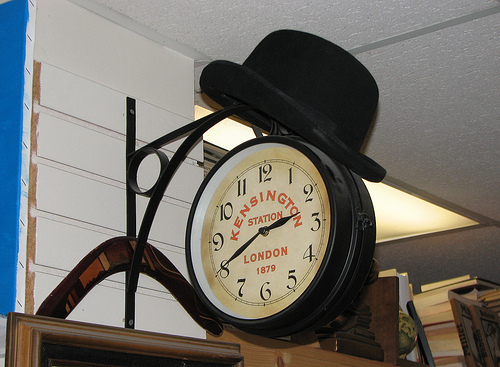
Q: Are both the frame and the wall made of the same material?
A: Yes, both the frame and the wall are made of wood.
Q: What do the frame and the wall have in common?
A: The material, both the frame and the wall are wooden.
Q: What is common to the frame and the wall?
A: The material, both the frame and the wall are wooden.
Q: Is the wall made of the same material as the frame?
A: Yes, both the wall and the frame are made of wood.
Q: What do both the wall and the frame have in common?
A: The material, both the wall and the frame are wooden.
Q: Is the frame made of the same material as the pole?
A: No, the frame is made of wood and the pole is made of metal.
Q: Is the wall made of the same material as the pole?
A: No, the wall is made of wood and the pole is made of metal.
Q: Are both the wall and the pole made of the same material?
A: No, the wall is made of wood and the pole is made of metal.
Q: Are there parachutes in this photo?
A: No, there are no parachutes.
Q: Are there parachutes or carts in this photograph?
A: No, there are no parachutes or carts.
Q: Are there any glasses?
A: No, there are no glasses.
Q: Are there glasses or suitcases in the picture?
A: No, there are no glasses or suitcases.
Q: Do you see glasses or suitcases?
A: No, there are no glasses or suitcases.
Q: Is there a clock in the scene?
A: Yes, there is a clock.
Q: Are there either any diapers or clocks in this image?
A: Yes, there is a clock.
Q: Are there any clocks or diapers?
A: Yes, there is a clock.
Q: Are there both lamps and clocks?
A: No, there is a clock but no lamps.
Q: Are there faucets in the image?
A: No, there are no faucets.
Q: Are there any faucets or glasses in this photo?
A: No, there are no faucets or glasses.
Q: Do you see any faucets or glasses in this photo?
A: No, there are no faucets or glasses.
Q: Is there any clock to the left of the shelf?
A: Yes, there is a clock to the left of the shelf.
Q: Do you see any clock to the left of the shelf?
A: Yes, there is a clock to the left of the shelf.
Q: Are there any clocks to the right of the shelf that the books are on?
A: No, the clock is to the left of the shelf.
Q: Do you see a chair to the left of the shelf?
A: No, there is a clock to the left of the shelf.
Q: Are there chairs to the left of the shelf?
A: No, there is a clock to the left of the shelf.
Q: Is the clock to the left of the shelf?
A: Yes, the clock is to the left of the shelf.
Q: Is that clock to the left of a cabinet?
A: No, the clock is to the left of the shelf.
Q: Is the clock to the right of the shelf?
A: No, the clock is to the left of the shelf.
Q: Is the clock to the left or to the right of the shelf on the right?
A: The clock is to the left of the shelf.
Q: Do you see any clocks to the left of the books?
A: Yes, there is a clock to the left of the books.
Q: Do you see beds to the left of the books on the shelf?
A: No, there is a clock to the left of the books.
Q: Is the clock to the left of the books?
A: Yes, the clock is to the left of the books.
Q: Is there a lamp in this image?
A: No, there are no lamps.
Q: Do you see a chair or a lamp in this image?
A: No, there are no lamps or chairs.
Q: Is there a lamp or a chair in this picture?
A: No, there are no lamps or chairs.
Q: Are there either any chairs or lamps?
A: No, there are no lamps or chairs.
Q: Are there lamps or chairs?
A: No, there are no lamps or chairs.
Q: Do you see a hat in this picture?
A: Yes, there is a hat.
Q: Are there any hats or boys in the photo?
A: Yes, there is a hat.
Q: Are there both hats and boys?
A: No, there is a hat but no boys.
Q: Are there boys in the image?
A: No, there are no boys.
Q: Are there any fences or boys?
A: No, there are no boys or fences.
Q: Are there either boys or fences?
A: No, there are no boys or fences.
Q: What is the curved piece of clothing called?
A: The clothing item is a hat.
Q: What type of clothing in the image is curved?
A: The clothing is a hat.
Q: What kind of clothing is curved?
A: The clothing is a hat.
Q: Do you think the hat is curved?
A: Yes, the hat is curved.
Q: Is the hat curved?
A: Yes, the hat is curved.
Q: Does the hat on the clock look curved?
A: Yes, the hat is curved.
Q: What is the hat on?
A: The hat is on the clock.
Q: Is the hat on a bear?
A: No, the hat is on a clock.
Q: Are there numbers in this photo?
A: Yes, there are numbers.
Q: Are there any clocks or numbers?
A: Yes, there are numbers.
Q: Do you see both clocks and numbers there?
A: Yes, there are both numbers and a clock.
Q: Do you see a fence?
A: No, there are no fences.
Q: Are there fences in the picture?
A: No, there are no fences.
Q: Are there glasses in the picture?
A: No, there are no glasses.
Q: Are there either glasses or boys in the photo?
A: No, there are no glasses or boys.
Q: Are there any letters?
A: Yes, there are letters.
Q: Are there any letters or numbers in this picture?
A: Yes, there are letters.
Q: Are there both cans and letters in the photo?
A: No, there are letters but no cans.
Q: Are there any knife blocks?
A: No, there are no knife blocks.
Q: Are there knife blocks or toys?
A: No, there are no knife blocks or toys.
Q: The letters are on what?
A: The letters are on the clock.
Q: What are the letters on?
A: The letters are on the clock.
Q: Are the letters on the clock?
A: Yes, the letters are on the clock.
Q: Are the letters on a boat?
A: No, the letters are on the clock.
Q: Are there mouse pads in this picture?
A: No, there are no mouse pads.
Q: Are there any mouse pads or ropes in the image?
A: No, there are no mouse pads or ropes.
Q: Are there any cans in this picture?
A: No, there are no cans.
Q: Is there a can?
A: No, there are no cans.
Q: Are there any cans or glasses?
A: No, there are no cans or glasses.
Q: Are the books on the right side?
A: Yes, the books are on the right of the image.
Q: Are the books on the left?
A: No, the books are on the right of the image.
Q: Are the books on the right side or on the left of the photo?
A: The books are on the right of the image.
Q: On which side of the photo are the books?
A: The books are on the right of the image.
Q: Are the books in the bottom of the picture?
A: Yes, the books are in the bottom of the image.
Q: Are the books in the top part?
A: No, the books are in the bottom of the image.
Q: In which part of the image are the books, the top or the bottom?
A: The books are in the bottom of the image.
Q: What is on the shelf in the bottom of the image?
A: The books are on the shelf.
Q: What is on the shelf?
A: The books are on the shelf.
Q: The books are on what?
A: The books are on the shelf.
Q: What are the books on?
A: The books are on the shelf.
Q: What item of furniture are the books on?
A: The books are on the shelf.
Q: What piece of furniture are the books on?
A: The books are on the shelf.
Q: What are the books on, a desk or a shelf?
A: The books are on a shelf.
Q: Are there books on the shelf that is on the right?
A: Yes, there are books on the shelf.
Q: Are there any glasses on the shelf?
A: No, there are books on the shelf.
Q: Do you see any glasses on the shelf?
A: No, there are books on the shelf.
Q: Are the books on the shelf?
A: Yes, the books are on the shelf.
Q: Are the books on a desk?
A: No, the books are on the shelf.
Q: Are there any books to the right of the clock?
A: Yes, there are books to the right of the clock.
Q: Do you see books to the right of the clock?
A: Yes, there are books to the right of the clock.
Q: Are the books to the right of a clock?
A: Yes, the books are to the right of a clock.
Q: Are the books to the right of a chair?
A: No, the books are to the right of a clock.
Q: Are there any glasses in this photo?
A: No, there are no glasses.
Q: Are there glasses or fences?
A: No, there are no glasses or fences.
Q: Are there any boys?
A: No, there are no boys.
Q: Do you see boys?
A: No, there are no boys.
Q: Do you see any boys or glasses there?
A: No, there are no boys or glasses.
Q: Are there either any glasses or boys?
A: No, there are no boys or glasses.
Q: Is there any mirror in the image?
A: No, there are no mirrors.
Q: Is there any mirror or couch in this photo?
A: No, there are no mirrors or couches.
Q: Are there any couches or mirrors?
A: No, there are no mirrors or couches.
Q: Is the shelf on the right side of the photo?
A: Yes, the shelf is on the right of the image.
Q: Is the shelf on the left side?
A: No, the shelf is on the right of the image.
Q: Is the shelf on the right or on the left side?
A: The shelf is on the right of the image.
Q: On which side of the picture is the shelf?
A: The shelf is on the right of the image.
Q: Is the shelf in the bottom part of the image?
A: Yes, the shelf is in the bottom of the image.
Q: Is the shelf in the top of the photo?
A: No, the shelf is in the bottom of the image.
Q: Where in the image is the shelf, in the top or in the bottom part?
A: The shelf is in the bottom of the image.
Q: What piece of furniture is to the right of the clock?
A: The piece of furniture is a shelf.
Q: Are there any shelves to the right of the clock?
A: Yes, there is a shelf to the right of the clock.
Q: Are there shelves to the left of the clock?
A: No, the shelf is to the right of the clock.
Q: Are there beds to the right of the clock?
A: No, there is a shelf to the right of the clock.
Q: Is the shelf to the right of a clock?
A: Yes, the shelf is to the right of a clock.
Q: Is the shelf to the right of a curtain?
A: No, the shelf is to the right of a clock.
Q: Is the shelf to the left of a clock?
A: No, the shelf is to the right of a clock.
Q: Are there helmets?
A: No, there are no helmets.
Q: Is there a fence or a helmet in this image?
A: No, there are no helmets or fences.